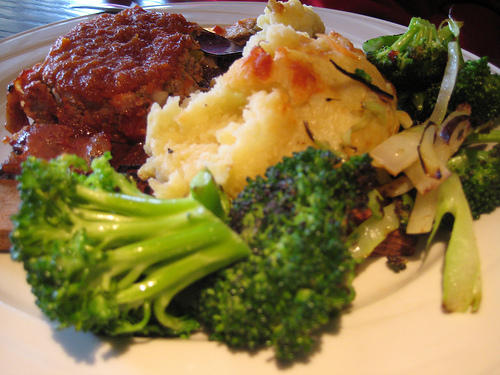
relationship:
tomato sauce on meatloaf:
[3, 5, 255, 180] [14, 10, 197, 134]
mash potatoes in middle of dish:
[139, 0, 405, 201] [1, 1, 499, 370]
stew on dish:
[8, 5, 260, 196] [1, 1, 499, 370]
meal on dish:
[6, 0, 498, 370] [1, 1, 499, 370]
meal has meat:
[6, 0, 498, 370] [6, 5, 258, 195]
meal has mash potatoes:
[6, 0, 498, 370] [136, 2, 418, 205]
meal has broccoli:
[6, 0, 498, 370] [15, 149, 253, 346]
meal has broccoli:
[6, 0, 498, 370] [183, 146, 386, 367]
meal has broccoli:
[6, 0, 498, 370] [442, 142, 499, 219]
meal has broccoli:
[6, 0, 498, 370] [365, 13, 463, 112]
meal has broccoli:
[6, 0, 498, 370] [362, 18, 456, 89]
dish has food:
[1, 1, 499, 370] [2, 2, 497, 367]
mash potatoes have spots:
[136, 2, 418, 205] [243, 44, 320, 95]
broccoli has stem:
[15, 149, 253, 346] [104, 187, 250, 316]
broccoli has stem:
[362, 18, 456, 89] [391, 16, 439, 52]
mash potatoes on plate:
[136, 2, 418, 205] [1, 1, 499, 371]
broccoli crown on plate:
[15, 149, 253, 346] [1, 1, 499, 371]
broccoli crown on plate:
[183, 146, 386, 367] [1, 1, 499, 371]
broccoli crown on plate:
[362, 18, 456, 89] [1, 1, 499, 371]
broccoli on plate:
[365, 13, 463, 112] [1, 1, 499, 371]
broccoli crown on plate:
[442, 142, 499, 219] [1, 1, 499, 371]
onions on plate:
[350, 37, 488, 315] [1, 1, 499, 371]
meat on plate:
[6, 5, 258, 195] [1, 1, 499, 371]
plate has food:
[1, 1, 499, 371] [2, 2, 497, 367]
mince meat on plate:
[6, 5, 258, 195] [1, 1, 499, 371]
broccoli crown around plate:
[15, 149, 253, 346] [1, 1, 499, 371]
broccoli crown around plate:
[183, 146, 386, 367] [1, 1, 499, 371]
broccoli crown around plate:
[442, 123, 498, 219] [1, 1, 499, 371]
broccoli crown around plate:
[421, 54, 499, 119] [1, 1, 499, 371]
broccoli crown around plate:
[366, 18, 465, 90] [1, 1, 499, 371]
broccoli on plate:
[15, 149, 253, 346] [1, 1, 499, 371]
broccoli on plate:
[183, 146, 386, 367] [1, 1, 499, 371]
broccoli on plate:
[442, 142, 499, 219] [1, 1, 499, 371]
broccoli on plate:
[362, 18, 456, 89] [1, 1, 499, 371]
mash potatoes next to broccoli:
[136, 2, 418, 205] [15, 149, 253, 346]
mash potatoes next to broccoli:
[136, 2, 418, 205] [183, 146, 386, 367]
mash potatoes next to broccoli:
[136, 2, 418, 205] [442, 142, 499, 219]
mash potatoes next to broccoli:
[136, 2, 418, 205] [365, 13, 463, 112]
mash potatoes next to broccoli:
[136, 2, 418, 205] [362, 18, 456, 89]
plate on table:
[1, 1, 499, 371] [0, 1, 499, 71]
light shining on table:
[47, 0, 180, 17] [0, 1, 499, 71]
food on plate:
[2, 2, 497, 367] [1, 1, 499, 371]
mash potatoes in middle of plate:
[136, 2, 418, 205] [1, 1, 499, 371]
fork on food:
[66, 1, 247, 61] [2, 2, 497, 367]